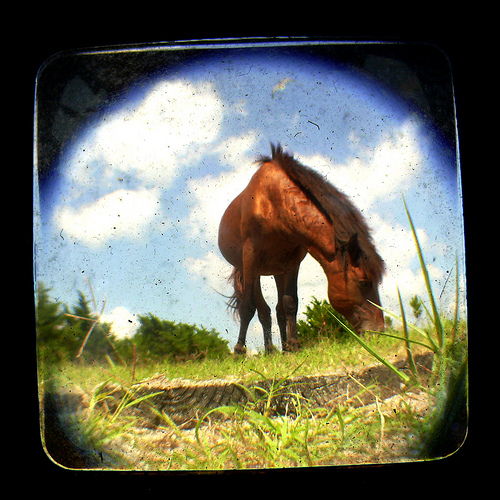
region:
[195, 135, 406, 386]
A horse eating grass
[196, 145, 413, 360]
horse in the grass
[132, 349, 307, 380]
green grass in a field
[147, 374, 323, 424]
wooden edging in the grass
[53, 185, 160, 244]
white cloud in the sky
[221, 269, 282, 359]
back legs of a horse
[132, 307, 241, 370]
green bush in the field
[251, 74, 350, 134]
blue sky behind the horse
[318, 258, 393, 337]
head of a horse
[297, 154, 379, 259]
mane of a horse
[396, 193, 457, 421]
weeds in the grass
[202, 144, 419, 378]
horse standing on the grass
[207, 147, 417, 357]
horse grazing in the grass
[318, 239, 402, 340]
head bent down to the ground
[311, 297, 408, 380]
long, bright green blade of grass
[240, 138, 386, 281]
dark hair along the neck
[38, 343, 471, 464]
green grass on the ground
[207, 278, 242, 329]
hair on the end of the tail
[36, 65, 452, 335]
bright white clouds in the sky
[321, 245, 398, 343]
head is touching the ground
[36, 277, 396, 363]
a couple of trees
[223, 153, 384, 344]
Brown horse eating grass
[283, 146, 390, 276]
Dark brown mane on horse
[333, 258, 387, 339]
Horse's head bent toward ground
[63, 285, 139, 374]
Tan twig in grass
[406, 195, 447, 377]
Green blades of grass in ground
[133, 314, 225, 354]
Thick green trees in distance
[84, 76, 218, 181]
Fluffy white cloud in blue sky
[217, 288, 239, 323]
Hair from horse's swishing tail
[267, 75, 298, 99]
Bird flying in sky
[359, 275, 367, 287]
Horse's eye looking at grass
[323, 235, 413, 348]
the head of a horse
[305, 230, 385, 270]
the ears of a horse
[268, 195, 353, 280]
the neck of a horse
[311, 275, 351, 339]
the jaw of a horse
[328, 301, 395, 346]
the mouth of a horse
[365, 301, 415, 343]
the nose of a horse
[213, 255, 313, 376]
the legs of a horse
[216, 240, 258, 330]
the tail of a horse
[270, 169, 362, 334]
the main of a horse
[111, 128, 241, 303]
clouds in the sky